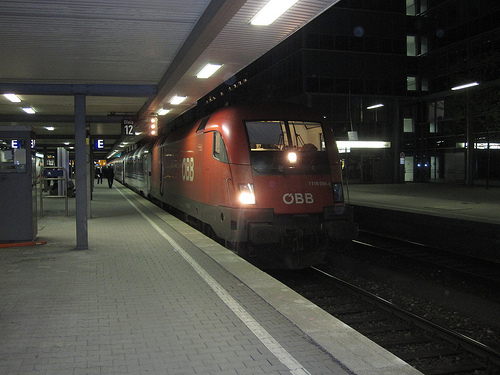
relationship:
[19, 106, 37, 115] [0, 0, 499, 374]
light at station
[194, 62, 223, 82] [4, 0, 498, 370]
light at station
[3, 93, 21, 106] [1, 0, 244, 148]
light on ceiling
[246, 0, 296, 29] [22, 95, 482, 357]
light at train station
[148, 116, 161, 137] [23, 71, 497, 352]
light at station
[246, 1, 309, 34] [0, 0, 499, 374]
light at station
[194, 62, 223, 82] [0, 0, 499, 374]
light at station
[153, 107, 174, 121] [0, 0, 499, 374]
light at station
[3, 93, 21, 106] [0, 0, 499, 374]
light at station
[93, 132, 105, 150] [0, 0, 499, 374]
light hanging in station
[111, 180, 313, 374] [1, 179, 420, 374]
line painted on platform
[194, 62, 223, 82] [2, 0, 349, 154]
light built into ceiling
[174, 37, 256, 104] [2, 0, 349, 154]
light built into ceiling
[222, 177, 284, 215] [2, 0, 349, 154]
light built into ceiling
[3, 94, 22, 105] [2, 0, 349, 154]
light built into ceiling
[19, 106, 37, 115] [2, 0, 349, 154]
light built into ceiling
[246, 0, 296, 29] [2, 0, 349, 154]
light built into ceiling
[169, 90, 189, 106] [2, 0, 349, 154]
light built into ceiling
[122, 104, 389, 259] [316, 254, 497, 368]
subway on tracks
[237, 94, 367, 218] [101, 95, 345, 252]
windows on subway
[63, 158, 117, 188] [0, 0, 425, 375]
people waiting to get subway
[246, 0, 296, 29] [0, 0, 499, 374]
light at station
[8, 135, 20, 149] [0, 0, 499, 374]
light in station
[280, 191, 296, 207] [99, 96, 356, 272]
white letter on train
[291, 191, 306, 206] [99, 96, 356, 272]
white letter on train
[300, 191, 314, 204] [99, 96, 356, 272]
white letter on train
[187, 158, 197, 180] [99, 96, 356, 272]
white letter on train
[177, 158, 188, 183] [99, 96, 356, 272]
white letter on train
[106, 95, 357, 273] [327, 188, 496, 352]
subway on track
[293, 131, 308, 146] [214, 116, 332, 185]
wiper on window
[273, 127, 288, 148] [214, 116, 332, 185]
wiper on window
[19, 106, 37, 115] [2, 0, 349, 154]
light on ceiling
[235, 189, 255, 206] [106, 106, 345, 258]
light on subway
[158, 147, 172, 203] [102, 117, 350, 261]
door on subway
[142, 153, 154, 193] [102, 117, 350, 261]
door on subway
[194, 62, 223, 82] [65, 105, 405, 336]
light above subway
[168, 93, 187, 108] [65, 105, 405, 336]
light above subway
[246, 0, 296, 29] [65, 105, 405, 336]
light above subway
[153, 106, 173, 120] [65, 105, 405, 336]
light above subway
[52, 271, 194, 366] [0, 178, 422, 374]
bricks on floor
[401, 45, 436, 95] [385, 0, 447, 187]
windows on building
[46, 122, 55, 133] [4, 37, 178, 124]
light on ceiling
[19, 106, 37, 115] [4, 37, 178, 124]
light on ceiling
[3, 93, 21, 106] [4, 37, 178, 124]
light on ceiling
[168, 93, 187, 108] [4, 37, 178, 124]
light on ceiling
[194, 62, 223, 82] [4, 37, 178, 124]
light on ceiling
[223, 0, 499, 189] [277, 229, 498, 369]
building next to tracks